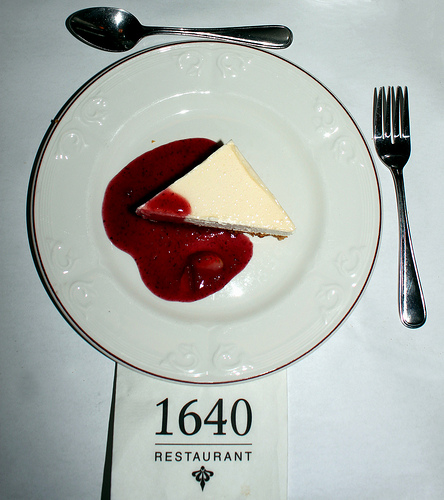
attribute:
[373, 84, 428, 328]
fork — silver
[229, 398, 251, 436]
number — bold, black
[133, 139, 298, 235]
cheescake — strawberry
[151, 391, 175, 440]
number — bold, black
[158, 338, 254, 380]
plate — white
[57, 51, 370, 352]
plate — white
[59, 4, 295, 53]
spoon — stainless steel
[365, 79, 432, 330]
fork — four prong, metal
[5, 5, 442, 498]
tablecloth — white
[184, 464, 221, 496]
emblem — decorative, black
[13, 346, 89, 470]
tablecloth — white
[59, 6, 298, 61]
spoon — shiny, metal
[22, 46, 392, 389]
plate — white, large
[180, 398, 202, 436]
six — black, bold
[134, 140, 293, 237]
cheesecake — strawberry